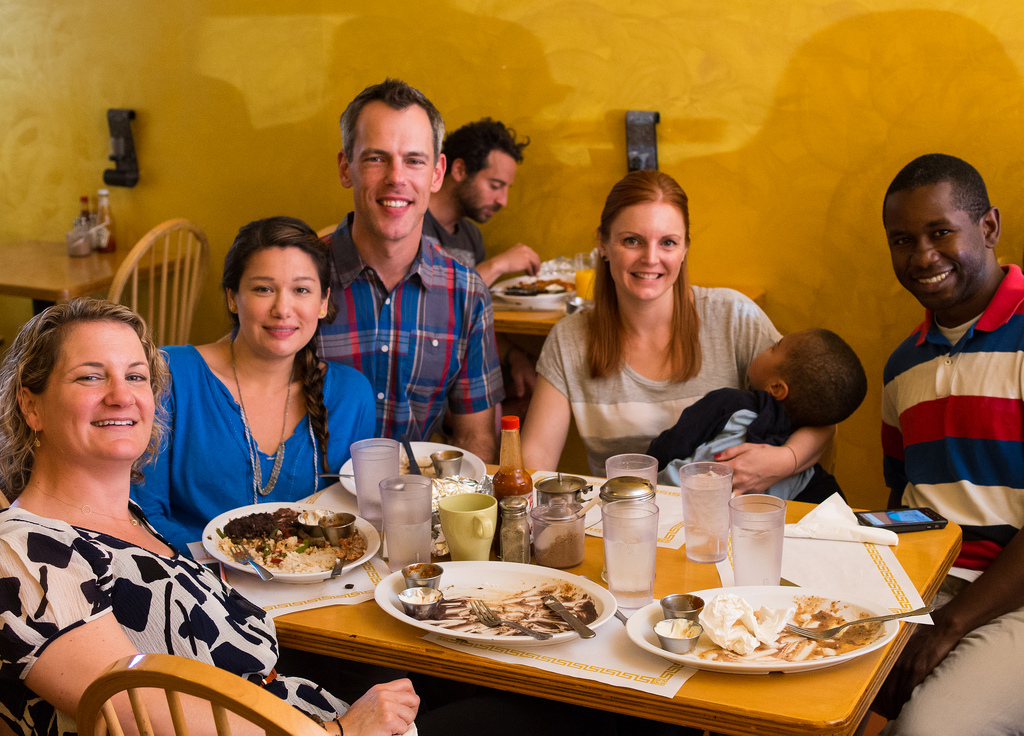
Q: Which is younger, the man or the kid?
A: The kid is younger than the man.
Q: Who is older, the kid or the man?
A: The man is older than the kid.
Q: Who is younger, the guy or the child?
A: The child is younger than the guy.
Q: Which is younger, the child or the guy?
A: The child is younger than the guy.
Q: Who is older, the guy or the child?
A: The guy is older than the child.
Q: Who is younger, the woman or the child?
A: The child is younger than the woman.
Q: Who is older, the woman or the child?
A: The woman is older than the child.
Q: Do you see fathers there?
A: No, there are no fathers.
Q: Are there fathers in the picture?
A: No, there are no fathers.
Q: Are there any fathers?
A: No, there are no fathers.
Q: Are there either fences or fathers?
A: No, there are no fathers or fences.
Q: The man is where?
A: The man is at the table.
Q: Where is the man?
A: The man is at the table.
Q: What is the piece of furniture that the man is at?
A: The piece of furniture is a table.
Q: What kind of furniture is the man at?
A: The man is at the table.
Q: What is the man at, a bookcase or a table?
A: The man is at a table.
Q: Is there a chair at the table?
A: No, there is a man at the table.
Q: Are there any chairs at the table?
A: No, there is a man at the table.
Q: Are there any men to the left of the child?
A: Yes, there is a man to the left of the child.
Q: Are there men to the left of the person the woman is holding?
A: Yes, there is a man to the left of the child.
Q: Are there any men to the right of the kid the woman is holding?
A: No, the man is to the left of the child.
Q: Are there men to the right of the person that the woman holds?
A: No, the man is to the left of the child.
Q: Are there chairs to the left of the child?
A: No, there is a man to the left of the child.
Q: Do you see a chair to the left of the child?
A: No, there is a man to the left of the child.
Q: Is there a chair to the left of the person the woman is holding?
A: No, there is a man to the left of the child.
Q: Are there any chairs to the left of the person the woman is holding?
A: No, there is a man to the left of the child.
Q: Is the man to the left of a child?
A: Yes, the man is to the left of a child.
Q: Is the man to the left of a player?
A: No, the man is to the left of a child.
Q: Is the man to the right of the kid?
A: No, the man is to the left of the kid.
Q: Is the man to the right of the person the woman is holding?
A: No, the man is to the left of the kid.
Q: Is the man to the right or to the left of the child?
A: The man is to the left of the child.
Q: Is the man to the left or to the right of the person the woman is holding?
A: The man is to the left of the child.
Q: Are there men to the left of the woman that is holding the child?
A: Yes, there is a man to the left of the woman.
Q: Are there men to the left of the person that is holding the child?
A: Yes, there is a man to the left of the woman.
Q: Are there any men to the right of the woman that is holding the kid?
A: No, the man is to the left of the woman.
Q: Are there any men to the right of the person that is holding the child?
A: No, the man is to the left of the woman.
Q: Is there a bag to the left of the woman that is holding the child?
A: No, there is a man to the left of the woman.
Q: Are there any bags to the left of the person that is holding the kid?
A: No, there is a man to the left of the woman.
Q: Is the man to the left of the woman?
A: Yes, the man is to the left of the woman.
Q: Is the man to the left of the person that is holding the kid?
A: Yes, the man is to the left of the woman.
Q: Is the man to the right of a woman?
A: No, the man is to the left of a woman.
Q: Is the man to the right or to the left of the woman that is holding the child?
A: The man is to the left of the woman.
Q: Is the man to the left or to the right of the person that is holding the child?
A: The man is to the left of the woman.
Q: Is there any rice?
A: Yes, there is rice.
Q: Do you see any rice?
A: Yes, there is rice.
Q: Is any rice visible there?
A: Yes, there is rice.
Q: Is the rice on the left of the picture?
A: Yes, the rice is on the left of the image.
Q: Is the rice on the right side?
A: No, the rice is on the left of the image.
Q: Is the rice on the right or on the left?
A: The rice is on the left of the image.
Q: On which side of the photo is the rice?
A: The rice is on the left of the image.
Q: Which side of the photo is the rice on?
A: The rice is on the left of the image.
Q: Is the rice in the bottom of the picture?
A: Yes, the rice is in the bottom of the image.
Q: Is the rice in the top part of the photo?
A: No, the rice is in the bottom of the image.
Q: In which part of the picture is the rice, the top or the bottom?
A: The rice is in the bottom of the image.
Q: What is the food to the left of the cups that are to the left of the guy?
A: The food is rice.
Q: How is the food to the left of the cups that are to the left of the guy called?
A: The food is rice.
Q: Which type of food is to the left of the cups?
A: The food is rice.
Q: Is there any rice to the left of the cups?
A: Yes, there is rice to the left of the cups.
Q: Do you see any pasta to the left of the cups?
A: No, there is rice to the left of the cups.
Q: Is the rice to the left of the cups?
A: Yes, the rice is to the left of the cups.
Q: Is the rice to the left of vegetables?
A: No, the rice is to the left of the cups.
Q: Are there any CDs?
A: No, there are no cds.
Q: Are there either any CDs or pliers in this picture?
A: No, there are no CDs or pliers.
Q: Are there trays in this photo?
A: No, there are no trays.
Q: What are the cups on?
A: The cups are on the table.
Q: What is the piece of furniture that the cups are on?
A: The piece of furniture is a table.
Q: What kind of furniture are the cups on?
A: The cups are on the table.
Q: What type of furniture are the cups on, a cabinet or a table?
A: The cups are on a table.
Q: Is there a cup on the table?
A: Yes, there are cups on the table.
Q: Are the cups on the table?
A: Yes, the cups are on the table.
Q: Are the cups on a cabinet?
A: No, the cups are on the table.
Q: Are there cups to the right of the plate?
A: Yes, there are cups to the right of the plate.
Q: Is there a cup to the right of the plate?
A: Yes, there are cups to the right of the plate.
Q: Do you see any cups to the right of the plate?
A: Yes, there are cups to the right of the plate.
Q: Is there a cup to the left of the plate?
A: No, the cups are to the right of the plate.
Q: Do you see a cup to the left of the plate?
A: No, the cups are to the right of the plate.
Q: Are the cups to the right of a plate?
A: Yes, the cups are to the right of a plate.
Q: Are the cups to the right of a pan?
A: No, the cups are to the right of a plate.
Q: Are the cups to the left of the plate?
A: No, the cups are to the right of the plate.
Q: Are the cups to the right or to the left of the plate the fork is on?
A: The cups are to the right of the plate.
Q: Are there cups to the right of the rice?
A: Yes, there are cups to the right of the rice.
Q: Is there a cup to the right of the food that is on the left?
A: Yes, there are cups to the right of the rice.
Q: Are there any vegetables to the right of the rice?
A: No, there are cups to the right of the rice.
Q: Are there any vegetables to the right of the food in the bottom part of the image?
A: No, there are cups to the right of the rice.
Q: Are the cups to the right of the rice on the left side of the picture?
A: Yes, the cups are to the right of the rice.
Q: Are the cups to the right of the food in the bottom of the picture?
A: Yes, the cups are to the right of the rice.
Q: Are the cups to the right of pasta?
A: No, the cups are to the right of the rice.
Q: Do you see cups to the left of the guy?
A: Yes, there are cups to the left of the guy.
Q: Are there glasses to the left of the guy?
A: No, there are cups to the left of the guy.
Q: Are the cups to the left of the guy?
A: Yes, the cups are to the left of the guy.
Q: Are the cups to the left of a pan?
A: No, the cups are to the left of the guy.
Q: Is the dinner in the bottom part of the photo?
A: Yes, the dinner is in the bottom of the image.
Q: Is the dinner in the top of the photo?
A: No, the dinner is in the bottom of the image.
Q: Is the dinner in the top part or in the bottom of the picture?
A: The dinner is in the bottom of the image.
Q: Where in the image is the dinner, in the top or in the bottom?
A: The dinner is in the bottom of the image.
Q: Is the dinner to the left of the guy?
A: Yes, the dinner is to the left of the guy.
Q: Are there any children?
A: Yes, there is a child.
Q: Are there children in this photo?
A: Yes, there is a child.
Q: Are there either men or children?
A: Yes, there is a child.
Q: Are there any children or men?
A: Yes, there is a child.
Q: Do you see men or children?
A: Yes, there is a child.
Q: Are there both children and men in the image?
A: Yes, there are both a child and a man.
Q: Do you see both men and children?
A: Yes, there are both a child and a man.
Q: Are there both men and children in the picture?
A: Yes, there are both a child and a man.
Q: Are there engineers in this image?
A: No, there are no engineers.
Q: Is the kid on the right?
A: Yes, the kid is on the right of the image.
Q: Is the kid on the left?
A: No, the kid is on the right of the image.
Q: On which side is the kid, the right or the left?
A: The kid is on the right of the image.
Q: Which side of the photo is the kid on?
A: The kid is on the right of the image.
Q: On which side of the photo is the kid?
A: The kid is on the right of the image.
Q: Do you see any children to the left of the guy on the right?
A: Yes, there is a child to the left of the guy.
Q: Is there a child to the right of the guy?
A: No, the child is to the left of the guy.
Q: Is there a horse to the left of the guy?
A: No, there is a child to the left of the guy.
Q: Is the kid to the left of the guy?
A: Yes, the kid is to the left of the guy.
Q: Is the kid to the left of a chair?
A: No, the kid is to the left of the guy.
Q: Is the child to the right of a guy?
A: No, the child is to the left of a guy.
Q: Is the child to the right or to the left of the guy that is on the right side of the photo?
A: The child is to the left of the guy.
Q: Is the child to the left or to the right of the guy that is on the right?
A: The child is to the left of the guy.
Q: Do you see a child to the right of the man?
A: Yes, there is a child to the right of the man.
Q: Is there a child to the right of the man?
A: Yes, there is a child to the right of the man.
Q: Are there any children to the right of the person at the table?
A: Yes, there is a child to the right of the man.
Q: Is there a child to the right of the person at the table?
A: Yes, there is a child to the right of the man.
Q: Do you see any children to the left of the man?
A: No, the child is to the right of the man.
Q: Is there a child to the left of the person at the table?
A: No, the child is to the right of the man.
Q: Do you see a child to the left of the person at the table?
A: No, the child is to the right of the man.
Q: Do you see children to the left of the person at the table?
A: No, the child is to the right of the man.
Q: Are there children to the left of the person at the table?
A: No, the child is to the right of the man.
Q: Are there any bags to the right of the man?
A: No, there is a child to the right of the man.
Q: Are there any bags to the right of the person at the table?
A: No, there is a child to the right of the man.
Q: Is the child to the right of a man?
A: Yes, the child is to the right of a man.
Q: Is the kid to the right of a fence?
A: No, the kid is to the right of a man.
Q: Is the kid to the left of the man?
A: No, the kid is to the right of the man.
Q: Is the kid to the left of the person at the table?
A: No, the kid is to the right of the man.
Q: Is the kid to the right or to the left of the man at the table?
A: The kid is to the right of the man.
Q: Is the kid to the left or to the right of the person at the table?
A: The kid is to the right of the man.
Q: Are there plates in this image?
A: Yes, there is a plate.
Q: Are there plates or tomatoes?
A: Yes, there is a plate.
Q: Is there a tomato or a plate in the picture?
A: Yes, there is a plate.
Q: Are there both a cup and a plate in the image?
A: Yes, there are both a plate and a cup.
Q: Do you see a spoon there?
A: No, there are no spoons.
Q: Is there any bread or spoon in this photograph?
A: No, there are no spoons or breads.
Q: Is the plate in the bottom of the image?
A: Yes, the plate is in the bottom of the image.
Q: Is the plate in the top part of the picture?
A: No, the plate is in the bottom of the image.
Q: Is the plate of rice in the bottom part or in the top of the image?
A: The plate is in the bottom of the image.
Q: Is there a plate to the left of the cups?
A: Yes, there is a plate to the left of the cups.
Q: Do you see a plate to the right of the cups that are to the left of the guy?
A: No, the plate is to the left of the cups.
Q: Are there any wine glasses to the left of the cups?
A: No, there is a plate to the left of the cups.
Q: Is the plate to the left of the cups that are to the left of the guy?
A: Yes, the plate is to the left of the cups.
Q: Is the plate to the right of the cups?
A: No, the plate is to the left of the cups.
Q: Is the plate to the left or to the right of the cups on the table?
A: The plate is to the left of the cups.